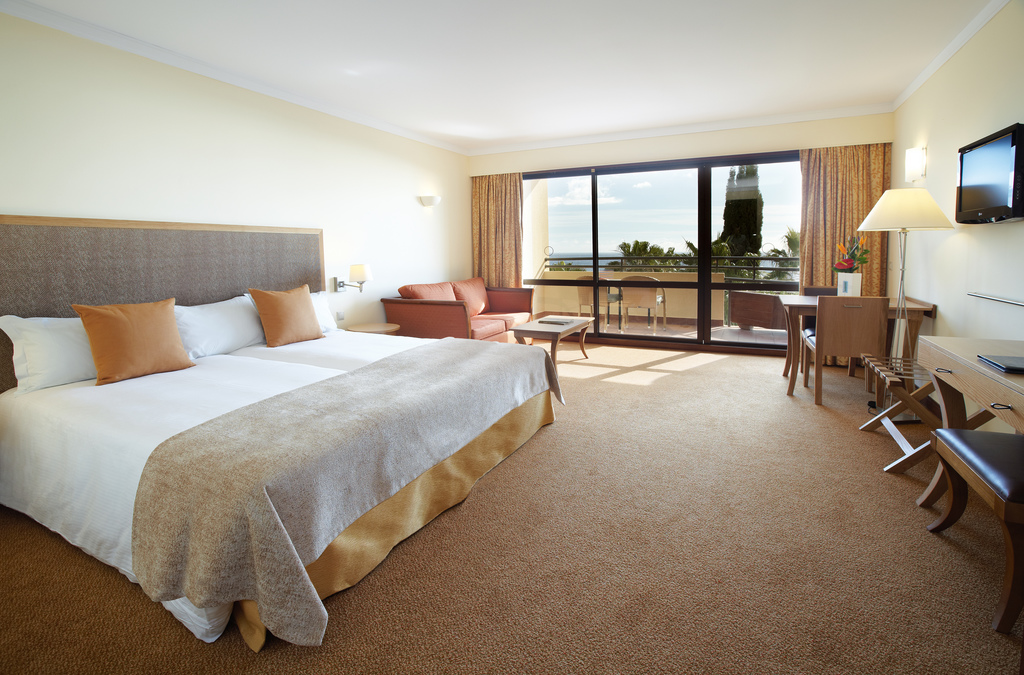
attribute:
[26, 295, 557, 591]
bed — large , white , gold 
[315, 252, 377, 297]
light — white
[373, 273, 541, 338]
sofa — red 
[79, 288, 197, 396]
pillow — tan 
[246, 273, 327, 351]
pillow — tan 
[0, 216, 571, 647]
bed — large 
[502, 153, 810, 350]
windows — large 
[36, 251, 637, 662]
sheets — white 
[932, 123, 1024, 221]
tv — black 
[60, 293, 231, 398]
pillow — brown 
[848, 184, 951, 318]
lamp — white